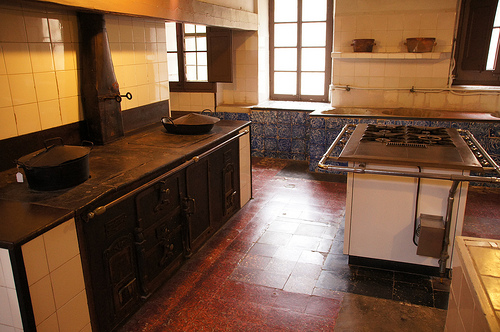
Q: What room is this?
A: Kitchen.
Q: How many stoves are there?
A: One.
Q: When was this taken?
A: During the day.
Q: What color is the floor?
A: Brown.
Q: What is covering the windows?
A: Nothing.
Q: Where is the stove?
A: In the island.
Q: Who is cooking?
A: No one.